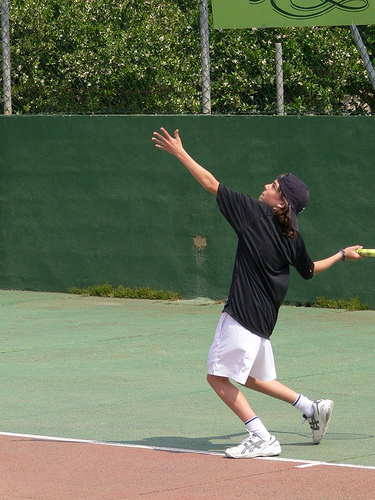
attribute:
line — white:
[14, 430, 373, 476]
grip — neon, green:
[357, 247, 373, 258]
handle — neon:
[357, 245, 374, 259]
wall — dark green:
[4, 113, 374, 298]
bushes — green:
[8, 4, 370, 114]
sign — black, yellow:
[200, 1, 373, 36]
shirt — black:
[215, 181, 319, 335]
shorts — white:
[205, 310, 277, 385]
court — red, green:
[12, 305, 213, 430]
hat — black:
[272, 168, 311, 231]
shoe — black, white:
[301, 395, 333, 447]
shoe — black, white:
[224, 431, 283, 461]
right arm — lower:
[305, 244, 364, 282]